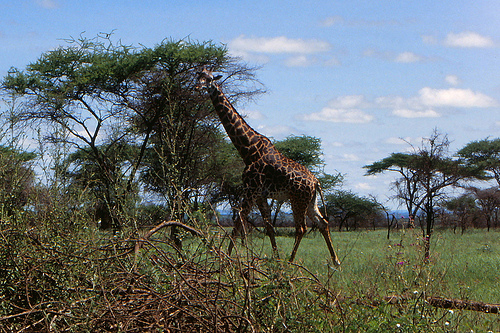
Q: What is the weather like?
A: It is cloudy.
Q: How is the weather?
A: It is cloudy.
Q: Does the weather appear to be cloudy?
A: Yes, it is cloudy.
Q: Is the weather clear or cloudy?
A: It is cloudy.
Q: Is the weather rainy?
A: No, it is cloudy.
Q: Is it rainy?
A: No, it is cloudy.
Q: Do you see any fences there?
A: No, there are no fences.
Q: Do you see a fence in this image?
A: No, there are no fences.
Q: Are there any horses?
A: No, there are no horses.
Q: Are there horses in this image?
A: No, there are no horses.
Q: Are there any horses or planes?
A: No, there are no horses or planes.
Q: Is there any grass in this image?
A: Yes, there is grass.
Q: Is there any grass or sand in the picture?
A: Yes, there is grass.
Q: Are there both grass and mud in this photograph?
A: No, there is grass but no mud.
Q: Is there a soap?
A: No, there are no soaps.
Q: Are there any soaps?
A: No, there are no soaps.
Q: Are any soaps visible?
A: No, there are no soaps.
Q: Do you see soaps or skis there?
A: No, there are no soaps or skis.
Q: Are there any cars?
A: No, there are no cars.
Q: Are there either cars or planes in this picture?
A: No, there are no cars or planes.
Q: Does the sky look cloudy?
A: Yes, the sky is cloudy.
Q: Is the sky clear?
A: No, the sky is cloudy.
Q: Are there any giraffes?
A: Yes, there is a giraffe.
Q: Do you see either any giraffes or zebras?
A: Yes, there is a giraffe.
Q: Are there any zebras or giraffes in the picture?
A: Yes, there is a giraffe.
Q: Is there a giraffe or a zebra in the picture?
A: Yes, there is a giraffe.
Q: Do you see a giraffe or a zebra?
A: Yes, there is a giraffe.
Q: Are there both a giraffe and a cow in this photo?
A: No, there is a giraffe but no cows.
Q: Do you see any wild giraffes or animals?
A: Yes, there is a wild giraffe.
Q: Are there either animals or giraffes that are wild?
A: Yes, the giraffe is wild.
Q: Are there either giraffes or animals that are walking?
A: Yes, the giraffe is walking.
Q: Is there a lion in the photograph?
A: No, there are no lions.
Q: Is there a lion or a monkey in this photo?
A: No, there are no lions or monkeys.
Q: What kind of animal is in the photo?
A: The animal is a giraffe.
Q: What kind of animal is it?
A: The animal is a giraffe.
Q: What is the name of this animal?
A: This is a giraffe.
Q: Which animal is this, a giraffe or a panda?
A: This is a giraffe.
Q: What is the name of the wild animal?
A: The animal is a giraffe.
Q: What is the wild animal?
A: The animal is a giraffe.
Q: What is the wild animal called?
A: The animal is a giraffe.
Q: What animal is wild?
A: The animal is a giraffe.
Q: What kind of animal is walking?
A: The animal is a giraffe.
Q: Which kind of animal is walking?
A: The animal is a giraffe.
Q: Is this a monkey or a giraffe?
A: This is a giraffe.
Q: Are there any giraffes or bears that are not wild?
A: No, there is a giraffe but it is wild.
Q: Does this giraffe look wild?
A: Yes, the giraffe is wild.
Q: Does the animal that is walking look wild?
A: Yes, the giraffe is wild.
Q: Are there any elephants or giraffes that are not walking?
A: No, there is a giraffe but it is walking.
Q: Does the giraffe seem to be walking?
A: Yes, the giraffe is walking.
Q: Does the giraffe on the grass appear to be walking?
A: Yes, the giraffe is walking.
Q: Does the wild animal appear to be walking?
A: Yes, the giraffe is walking.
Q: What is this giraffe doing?
A: The giraffe is walking.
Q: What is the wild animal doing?
A: The giraffe is walking.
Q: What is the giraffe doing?
A: The giraffe is walking.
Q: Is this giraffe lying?
A: No, the giraffe is walking.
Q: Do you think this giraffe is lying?
A: No, the giraffe is walking.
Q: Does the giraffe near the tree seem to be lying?
A: No, the giraffe is walking.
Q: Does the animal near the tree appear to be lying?
A: No, the giraffe is walking.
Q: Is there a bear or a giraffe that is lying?
A: No, there is a giraffe but it is walking.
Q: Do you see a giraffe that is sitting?
A: No, there is a giraffe but it is walking.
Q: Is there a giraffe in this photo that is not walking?
A: No, there is a giraffe but it is walking.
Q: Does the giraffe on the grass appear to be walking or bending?
A: The giraffe is walking.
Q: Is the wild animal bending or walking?
A: The giraffe is walking.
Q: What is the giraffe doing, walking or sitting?
A: The giraffe is walking.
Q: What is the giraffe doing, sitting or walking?
A: The giraffe is walking.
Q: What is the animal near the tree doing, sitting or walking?
A: The giraffe is walking.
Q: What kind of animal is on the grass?
A: The animal is a giraffe.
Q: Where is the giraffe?
A: The giraffe is on the grass.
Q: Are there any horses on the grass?
A: No, there is a giraffe on the grass.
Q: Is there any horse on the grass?
A: No, there is a giraffe on the grass.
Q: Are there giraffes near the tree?
A: Yes, there is a giraffe near the tree.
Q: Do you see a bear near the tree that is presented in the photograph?
A: No, there is a giraffe near the tree.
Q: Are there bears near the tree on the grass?
A: No, there is a giraffe near the tree.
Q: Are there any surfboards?
A: No, there are no surfboards.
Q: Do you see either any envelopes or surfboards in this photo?
A: No, there are no surfboards or envelopes.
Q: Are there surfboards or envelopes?
A: No, there are no surfboards or envelopes.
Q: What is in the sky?
A: The clouds are in the sky.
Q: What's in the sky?
A: The clouds are in the sky.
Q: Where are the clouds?
A: The clouds are in the sky.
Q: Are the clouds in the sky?
A: Yes, the clouds are in the sky.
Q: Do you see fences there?
A: No, there are no fences.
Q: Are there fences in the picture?
A: No, there are no fences.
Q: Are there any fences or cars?
A: No, there are no fences or cars.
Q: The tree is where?
A: The tree is on the grass.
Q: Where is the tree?
A: The tree is on the grass.